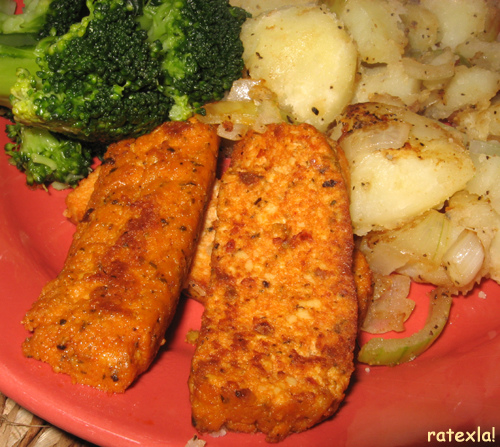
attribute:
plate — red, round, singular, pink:
[355, 268, 498, 447]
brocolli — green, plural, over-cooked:
[1, 0, 240, 138]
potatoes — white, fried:
[346, 0, 499, 278]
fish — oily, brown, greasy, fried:
[193, 124, 356, 424]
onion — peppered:
[363, 327, 439, 366]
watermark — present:
[426, 427, 494, 444]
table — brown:
[1, 396, 86, 446]